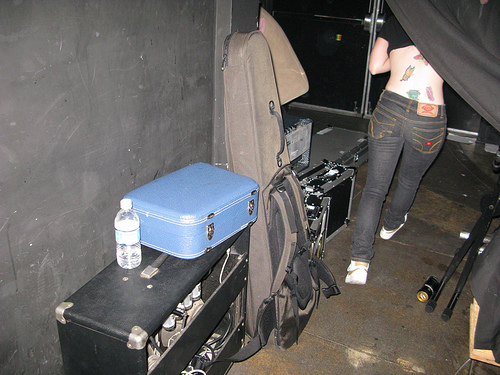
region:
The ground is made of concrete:
[335, 302, 405, 353]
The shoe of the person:
[342, 253, 382, 294]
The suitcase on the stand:
[117, 157, 266, 261]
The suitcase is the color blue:
[118, 158, 264, 263]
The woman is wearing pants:
[346, 85, 452, 265]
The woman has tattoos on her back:
[389, 48, 441, 106]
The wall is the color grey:
[14, 15, 198, 157]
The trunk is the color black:
[292, 152, 357, 244]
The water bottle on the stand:
[103, 195, 148, 270]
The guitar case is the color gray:
[221, 23, 345, 365]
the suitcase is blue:
[121, 133, 266, 248]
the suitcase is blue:
[128, 148, 304, 295]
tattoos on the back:
[383, 33, 454, 133]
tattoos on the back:
[353, 38, 476, 167]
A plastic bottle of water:
[113, 199, 139, 269]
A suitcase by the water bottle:
[126, 159, 259, 256]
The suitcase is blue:
[124, 161, 260, 254]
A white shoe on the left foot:
[342, 259, 370, 285]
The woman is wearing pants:
[348, 92, 445, 264]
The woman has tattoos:
[398, 53, 437, 100]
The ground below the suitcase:
[231, 148, 496, 374]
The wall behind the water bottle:
[1, 1, 212, 373]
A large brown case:
[221, 30, 322, 345]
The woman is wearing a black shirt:
[378, 7, 426, 47]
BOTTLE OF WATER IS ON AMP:
[111, 200, 161, 277]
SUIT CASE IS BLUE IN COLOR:
[130, 158, 267, 256]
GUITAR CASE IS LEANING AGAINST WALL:
[220, 28, 314, 358]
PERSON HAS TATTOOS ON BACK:
[399, 49, 446, 105]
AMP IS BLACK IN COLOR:
[54, 235, 276, 372]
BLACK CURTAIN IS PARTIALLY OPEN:
[390, 3, 490, 128]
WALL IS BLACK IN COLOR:
[5, 8, 192, 176]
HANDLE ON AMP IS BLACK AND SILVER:
[143, 251, 170, 282]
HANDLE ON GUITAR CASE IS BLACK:
[260, 99, 297, 167]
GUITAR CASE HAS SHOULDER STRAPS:
[261, 177, 335, 346]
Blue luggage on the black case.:
[115, 153, 257, 258]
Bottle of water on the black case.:
[107, 194, 144, 271]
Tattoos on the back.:
[390, 42, 440, 106]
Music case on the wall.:
[220, 25, 340, 354]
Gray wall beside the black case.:
[0, 3, 229, 374]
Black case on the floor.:
[54, 231, 249, 372]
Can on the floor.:
[415, 271, 441, 306]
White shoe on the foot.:
[343, 250, 368, 289]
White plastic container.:
[282, 117, 313, 172]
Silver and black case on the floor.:
[297, 155, 352, 245]